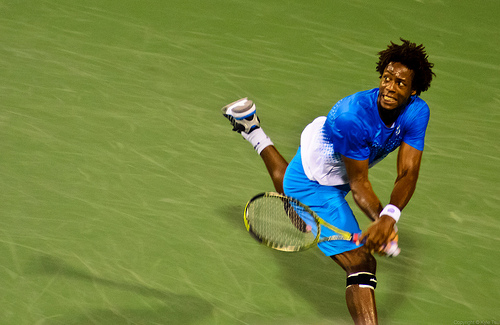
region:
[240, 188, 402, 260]
green and black tennis racket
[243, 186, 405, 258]
tennis racket in a man's hands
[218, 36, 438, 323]
tennis player in position to swing his racket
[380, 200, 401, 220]
white band around a man's wrist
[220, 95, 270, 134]
shoe with a white and gray bottom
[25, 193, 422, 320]
shadows on a tennis court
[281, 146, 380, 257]
blue shorts on a tennis player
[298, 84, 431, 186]
blue and white shirt on a tennis player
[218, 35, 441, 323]
man playing a tennis game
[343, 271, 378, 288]
black and white band on a man's leg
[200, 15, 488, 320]
A black man intensely playing a game of tennis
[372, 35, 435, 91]
Short black hair on the man's head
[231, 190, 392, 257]
A yellow tennis racket in the man's hands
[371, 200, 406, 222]
A white sweat band on the man's wrist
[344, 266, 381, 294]
A black sweat band on the man's leg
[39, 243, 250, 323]
A black shadow on the green ground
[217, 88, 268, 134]
White and blue shoes on the man's feet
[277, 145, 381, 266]
A blue pair of shorts on the man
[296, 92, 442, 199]
A blue and white shirt on the man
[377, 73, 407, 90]
The man's eyes are open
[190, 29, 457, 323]
a man playing tennis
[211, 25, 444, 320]
a man running on a tennis court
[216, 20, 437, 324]
a man waiting for a tennis ball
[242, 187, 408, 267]
a man holding a tennis racquet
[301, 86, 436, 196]
a man wearing a blue and white shirt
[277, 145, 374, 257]
a man wearing blue shorts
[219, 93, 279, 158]
a man's sock and shoe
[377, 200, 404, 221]
a white wristband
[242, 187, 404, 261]
a tennis racquet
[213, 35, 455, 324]
a man looking up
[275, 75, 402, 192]
a blue and white shirt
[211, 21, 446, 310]
the player is running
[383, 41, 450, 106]
Man has black hair.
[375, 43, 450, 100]
Man has dreads on head.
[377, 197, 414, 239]
Man wearing white sweat band on wrist.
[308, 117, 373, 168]
Man wearing blue and white shirt.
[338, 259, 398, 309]
Black and white strap around man's knee.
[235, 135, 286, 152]
Man wearing white socks.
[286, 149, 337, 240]
Man wearing blue shorts.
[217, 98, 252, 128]
Man wearing white, gray, and blue shoes.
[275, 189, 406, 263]
Man holding tennis racket.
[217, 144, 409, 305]
Yellow and black tennis racket.